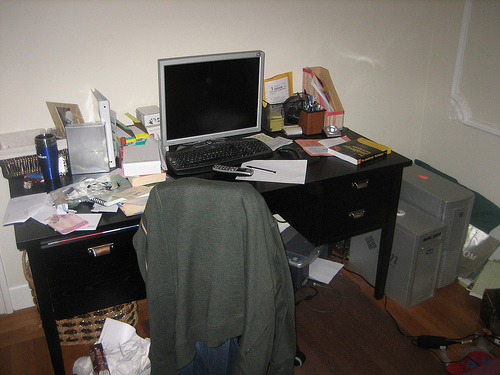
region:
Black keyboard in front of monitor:
[160, 136, 278, 172]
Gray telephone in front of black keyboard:
[210, 160, 254, 175]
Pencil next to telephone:
[244, 165, 277, 172]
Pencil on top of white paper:
[241, 160, 278, 175]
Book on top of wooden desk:
[324, 130, 396, 166]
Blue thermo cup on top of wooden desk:
[32, 131, 64, 188]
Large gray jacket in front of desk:
[135, 183, 297, 374]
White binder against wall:
[89, 84, 120, 166]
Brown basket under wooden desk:
[15, 253, 138, 346]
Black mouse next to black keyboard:
[276, 146, 302, 158]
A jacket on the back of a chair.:
[133, 176, 295, 369]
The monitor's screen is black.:
[156, 47, 262, 142]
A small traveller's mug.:
[34, 130, 60, 182]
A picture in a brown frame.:
[45, 97, 86, 122]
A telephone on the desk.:
[210, 160, 256, 179]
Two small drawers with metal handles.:
[311, 166, 401, 232]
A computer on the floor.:
[350, 210, 446, 307]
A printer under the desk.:
[275, 225, 340, 285]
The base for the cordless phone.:
[320, 120, 344, 139]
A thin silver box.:
[63, 120, 109, 172]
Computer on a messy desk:
[6, 52, 417, 362]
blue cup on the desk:
[30, 131, 64, 183]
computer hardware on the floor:
[340, 159, 474, 310]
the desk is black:
[0, 129, 435, 358]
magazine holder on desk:
[300, 64, 347, 129]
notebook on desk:
[87, 88, 119, 165]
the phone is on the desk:
[207, 155, 262, 180]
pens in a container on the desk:
[297, 87, 327, 134]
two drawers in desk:
[310, 164, 393, 241]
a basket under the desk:
[13, 252, 148, 347]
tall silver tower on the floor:
[402, 169, 478, 297]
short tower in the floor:
[352, 191, 442, 308]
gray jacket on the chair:
[134, 173, 304, 371]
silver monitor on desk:
[155, 45, 289, 137]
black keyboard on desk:
[162, 134, 269, 174]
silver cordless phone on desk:
[210, 160, 258, 179]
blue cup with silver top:
[30, 127, 65, 187]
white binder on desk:
[87, 85, 116, 167]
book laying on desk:
[328, 126, 393, 163]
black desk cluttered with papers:
[4, 110, 417, 354]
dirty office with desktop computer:
[15, 49, 490, 344]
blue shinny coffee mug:
[31, 131, 68, 185]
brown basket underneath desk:
[17, 248, 143, 348]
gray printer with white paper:
[274, 216, 362, 299]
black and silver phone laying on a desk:
[207, 156, 271, 183]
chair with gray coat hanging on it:
[130, 178, 307, 373]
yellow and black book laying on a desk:
[324, 132, 401, 172]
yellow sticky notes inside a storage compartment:
[265, 98, 304, 136]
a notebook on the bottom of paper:
[86, 185, 132, 214]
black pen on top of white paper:
[239, 157, 318, 187]